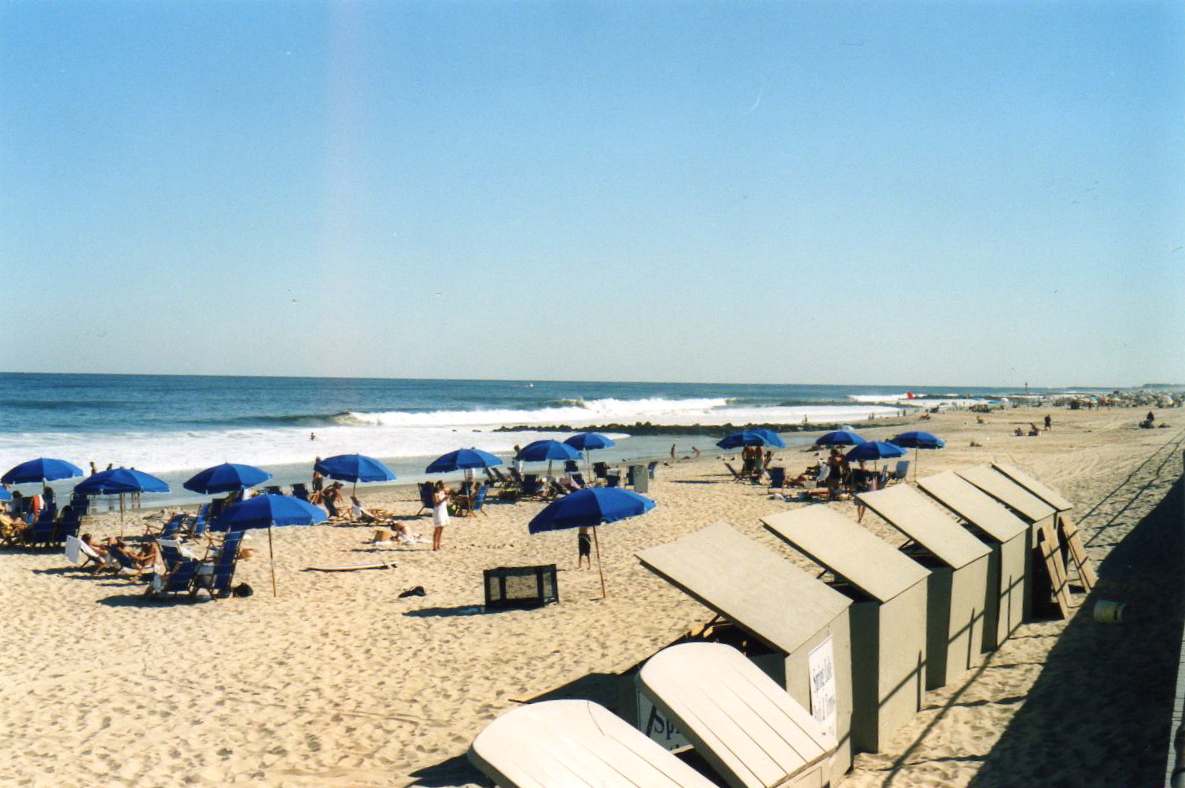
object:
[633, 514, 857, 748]
dumpster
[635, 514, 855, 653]
lid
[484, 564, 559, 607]
crib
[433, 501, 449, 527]
dress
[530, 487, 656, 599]
umbrella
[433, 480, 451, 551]
person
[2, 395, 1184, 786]
beach